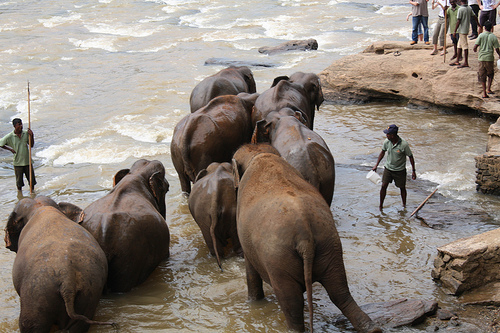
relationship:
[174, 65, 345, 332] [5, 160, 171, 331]
pack of brown elephants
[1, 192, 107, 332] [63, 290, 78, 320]
elephant has brown tail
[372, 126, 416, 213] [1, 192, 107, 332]
man bear elephant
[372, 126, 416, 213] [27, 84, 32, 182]
man holding a brown pole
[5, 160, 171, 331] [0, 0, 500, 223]
elephants in lake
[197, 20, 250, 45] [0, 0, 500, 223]
waves form in lake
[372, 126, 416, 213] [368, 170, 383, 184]
man holding bucket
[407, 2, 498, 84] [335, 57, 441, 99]
people standing on shore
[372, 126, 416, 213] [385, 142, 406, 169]
man in green shirt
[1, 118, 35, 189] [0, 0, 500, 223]
person standing lake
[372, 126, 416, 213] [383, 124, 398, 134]
man wearing blue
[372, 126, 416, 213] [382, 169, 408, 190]
man wearing shorts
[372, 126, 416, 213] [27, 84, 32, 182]
man holding stick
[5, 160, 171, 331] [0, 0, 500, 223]
elephants walking in lake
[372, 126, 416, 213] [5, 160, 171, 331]
man looking at elephants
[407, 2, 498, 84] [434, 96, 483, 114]
people standing on ledge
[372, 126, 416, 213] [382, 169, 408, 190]
man wearing brown shorts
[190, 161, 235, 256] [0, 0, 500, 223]
baby elephant in lake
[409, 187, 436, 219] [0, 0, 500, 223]
stick in lake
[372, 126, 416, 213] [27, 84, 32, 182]
man holding pole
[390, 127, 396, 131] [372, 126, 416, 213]
blue cap on man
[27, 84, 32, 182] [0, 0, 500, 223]
pole in lake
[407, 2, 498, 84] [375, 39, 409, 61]
people on rock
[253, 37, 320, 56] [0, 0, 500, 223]
rock in lake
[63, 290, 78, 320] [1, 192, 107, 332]
tail of elephant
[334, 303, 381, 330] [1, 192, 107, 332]
leg of elephant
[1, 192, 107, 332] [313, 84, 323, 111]
elephant has an ear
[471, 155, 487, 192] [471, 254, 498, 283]
edge of wall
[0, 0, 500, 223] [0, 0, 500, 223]
lake of a lake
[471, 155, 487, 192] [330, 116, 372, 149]
edge of a lake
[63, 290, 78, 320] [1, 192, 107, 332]
tail of a elephant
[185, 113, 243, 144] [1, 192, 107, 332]
body of elephant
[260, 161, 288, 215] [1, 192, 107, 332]
back of an elephant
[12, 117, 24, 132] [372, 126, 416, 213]
head of a man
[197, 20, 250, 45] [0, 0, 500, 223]
waves in lake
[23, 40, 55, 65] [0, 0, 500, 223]
brown muddy water in lake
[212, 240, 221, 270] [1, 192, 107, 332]
skinny tail on elephant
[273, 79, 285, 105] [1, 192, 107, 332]
hump on elephant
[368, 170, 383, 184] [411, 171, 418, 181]
jug in mans hand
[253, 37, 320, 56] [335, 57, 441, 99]
rock on shore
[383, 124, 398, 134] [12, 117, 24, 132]
blue on mans head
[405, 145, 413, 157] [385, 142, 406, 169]
short sleeved green shirt